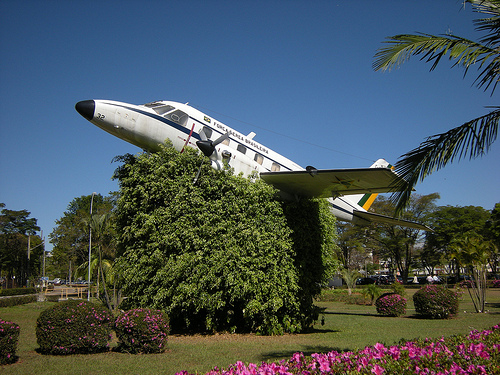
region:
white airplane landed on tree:
[76, 84, 436, 241]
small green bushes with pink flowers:
[12, 291, 175, 358]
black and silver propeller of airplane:
[177, 118, 234, 183]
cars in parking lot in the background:
[360, 253, 467, 288]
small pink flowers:
[347, 328, 496, 369]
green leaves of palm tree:
[420, 10, 499, 181]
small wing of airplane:
[266, 149, 416, 212]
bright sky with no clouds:
[229, 26, 339, 90]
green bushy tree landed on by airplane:
[137, 66, 325, 327]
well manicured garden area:
[58, 264, 472, 369]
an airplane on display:
[74, 97, 429, 228]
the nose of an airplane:
[71, 96, 131, 141]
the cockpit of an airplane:
[141, 97, 188, 147]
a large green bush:
[105, 140, 330, 335]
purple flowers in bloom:
[175, 326, 495, 371]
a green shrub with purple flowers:
[410, 280, 457, 315]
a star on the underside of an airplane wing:
[326, 170, 356, 190]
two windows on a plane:
[235, 143, 265, 165]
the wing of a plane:
[257, 165, 414, 195]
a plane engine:
[183, 123, 228, 173]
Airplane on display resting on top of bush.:
[72, 83, 439, 249]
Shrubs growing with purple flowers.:
[26, 295, 173, 361]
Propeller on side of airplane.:
[188, 123, 234, 192]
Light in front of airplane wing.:
[300, 160, 325, 182]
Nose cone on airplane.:
[71, 90, 100, 124]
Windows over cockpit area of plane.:
[143, 97, 193, 129]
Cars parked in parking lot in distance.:
[46, 274, 97, 289]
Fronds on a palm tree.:
[363, 15, 496, 221]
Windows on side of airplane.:
[236, 140, 288, 175]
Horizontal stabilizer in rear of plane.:
[351, 204, 435, 237]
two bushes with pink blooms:
[32, 294, 176, 359]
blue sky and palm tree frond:
[360, 22, 495, 98]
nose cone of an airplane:
[65, 86, 137, 145]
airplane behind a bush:
[66, 63, 358, 308]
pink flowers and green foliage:
[369, 328, 499, 373]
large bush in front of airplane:
[72, 85, 326, 309]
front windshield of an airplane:
[135, 90, 195, 130]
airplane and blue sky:
[63, 75, 412, 203]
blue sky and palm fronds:
[363, 1, 498, 99]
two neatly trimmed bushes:
[32, 292, 169, 364]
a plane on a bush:
[73, 79, 401, 234]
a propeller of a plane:
[194, 122, 230, 168]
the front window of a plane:
[148, 97, 190, 130]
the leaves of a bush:
[171, 205, 245, 278]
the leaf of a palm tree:
[393, 29, 491, 87]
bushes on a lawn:
[373, 285, 461, 322]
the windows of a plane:
[231, 139, 268, 165]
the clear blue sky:
[24, 46, 76, 81]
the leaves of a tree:
[433, 208, 487, 250]